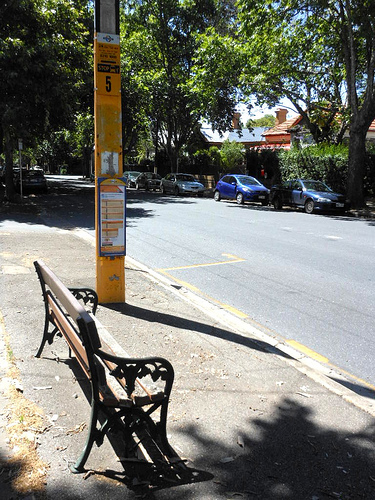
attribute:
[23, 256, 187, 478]
bench — wood, brown, wooden, existing, empty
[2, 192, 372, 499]
sidewalk — grey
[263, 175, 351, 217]
car — parked, white, existing, two door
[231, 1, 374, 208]
tree — green, existing, full of leaves, sunned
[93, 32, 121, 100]
sign — printed, yellow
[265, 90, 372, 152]
house — existing, orange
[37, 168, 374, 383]
road — paved, existing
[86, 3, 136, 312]
pole — yellow, signpost, existing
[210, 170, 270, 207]
car — blue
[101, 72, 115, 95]
number — black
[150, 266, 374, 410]
curb — yellow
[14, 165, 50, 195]
car — parked